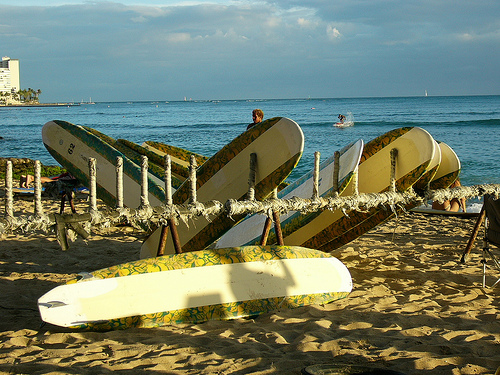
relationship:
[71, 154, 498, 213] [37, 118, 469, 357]
sticks holding up surfboards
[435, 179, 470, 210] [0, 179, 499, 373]
woman sitting beach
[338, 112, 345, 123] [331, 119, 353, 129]
man standing surfboard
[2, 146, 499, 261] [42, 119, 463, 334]
rack hold surfboards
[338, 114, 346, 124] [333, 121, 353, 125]
man on a surfboard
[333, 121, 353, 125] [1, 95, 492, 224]
surfboard in blue water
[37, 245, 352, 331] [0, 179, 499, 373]
surfboard on beach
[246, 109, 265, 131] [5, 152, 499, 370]
man at beach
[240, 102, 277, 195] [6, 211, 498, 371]
man at beach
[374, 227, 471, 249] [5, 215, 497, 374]
shadows on sand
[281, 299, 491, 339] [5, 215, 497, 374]
shadows on sand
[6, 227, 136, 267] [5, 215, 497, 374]
shadows on sand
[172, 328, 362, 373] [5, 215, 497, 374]
shadows on sand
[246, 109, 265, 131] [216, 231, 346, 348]
man has shadow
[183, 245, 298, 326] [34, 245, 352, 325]
shadow on surfboard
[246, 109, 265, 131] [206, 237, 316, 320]
man has shadow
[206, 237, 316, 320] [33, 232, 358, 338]
shadow on surfboard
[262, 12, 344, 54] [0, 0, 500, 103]
clouds in blue sky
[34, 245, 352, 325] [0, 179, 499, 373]
surfboard on beach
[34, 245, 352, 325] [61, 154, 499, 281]
surfboard near rack